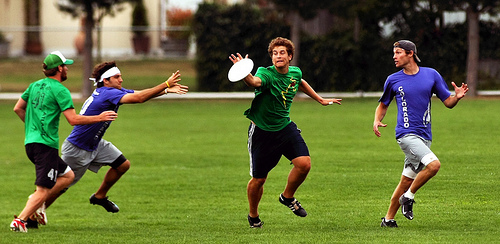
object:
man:
[228, 36, 343, 229]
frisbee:
[226, 57, 256, 82]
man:
[23, 60, 189, 230]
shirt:
[65, 86, 135, 152]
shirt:
[242, 65, 303, 131]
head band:
[88, 65, 121, 86]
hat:
[41, 51, 74, 72]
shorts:
[23, 141, 72, 189]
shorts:
[60, 137, 128, 189]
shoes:
[7, 217, 28, 233]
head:
[267, 37, 295, 68]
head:
[91, 60, 123, 89]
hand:
[321, 98, 343, 106]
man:
[372, 40, 469, 228]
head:
[392, 40, 417, 68]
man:
[7, 50, 118, 235]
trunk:
[464, 14, 479, 98]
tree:
[50, 0, 135, 98]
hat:
[393, 39, 421, 62]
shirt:
[20, 77, 76, 150]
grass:
[0, 92, 500, 244]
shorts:
[244, 120, 310, 179]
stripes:
[247, 123, 256, 176]